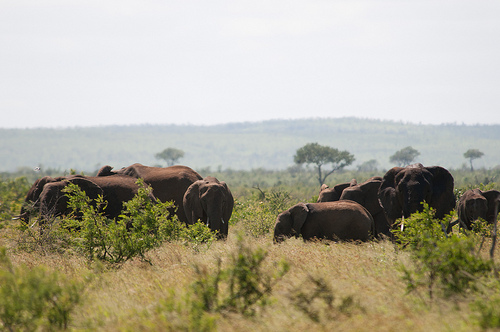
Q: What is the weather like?
A: It is cloudy.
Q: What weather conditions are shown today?
A: It is cloudy.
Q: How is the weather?
A: It is cloudy.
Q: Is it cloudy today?
A: Yes, it is cloudy.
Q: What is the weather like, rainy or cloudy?
A: It is cloudy.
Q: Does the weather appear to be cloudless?
A: No, it is cloudy.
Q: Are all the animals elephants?
A: Yes, all the animals are elephants.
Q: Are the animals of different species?
A: No, all the animals are elephants.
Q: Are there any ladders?
A: No, there are no ladders.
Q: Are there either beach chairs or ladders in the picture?
A: No, there are no ladders or beach chairs.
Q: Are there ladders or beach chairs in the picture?
A: No, there are no ladders or beach chairs.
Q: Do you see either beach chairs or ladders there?
A: No, there are no ladders or beach chairs.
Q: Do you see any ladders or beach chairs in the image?
A: No, there are no ladders or beach chairs.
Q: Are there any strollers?
A: No, there are no strollers.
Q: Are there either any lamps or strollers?
A: No, there are no strollers or lamps.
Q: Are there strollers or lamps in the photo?
A: No, there are no strollers or lamps.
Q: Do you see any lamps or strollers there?
A: No, there are no strollers or lamps.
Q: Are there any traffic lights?
A: No, there are no traffic lights.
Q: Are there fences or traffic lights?
A: No, there are no traffic lights or fences.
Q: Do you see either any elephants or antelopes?
A: Yes, there is an elephant.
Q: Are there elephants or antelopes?
A: Yes, there is an elephant.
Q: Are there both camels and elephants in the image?
A: No, there is an elephant but no camels.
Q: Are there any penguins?
A: No, there are no penguins.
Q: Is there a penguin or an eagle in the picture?
A: No, there are no penguins or eagles.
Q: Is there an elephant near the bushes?
A: Yes, there is an elephant near the bushes.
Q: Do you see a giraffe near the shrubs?
A: No, there is an elephant near the shrubs.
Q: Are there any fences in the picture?
A: No, there are no fences.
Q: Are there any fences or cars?
A: No, there are no fences or cars.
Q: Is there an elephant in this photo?
A: Yes, there is an elephant.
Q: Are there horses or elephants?
A: Yes, there is an elephant.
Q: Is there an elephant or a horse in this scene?
A: Yes, there is an elephant.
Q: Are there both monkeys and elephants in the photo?
A: No, there is an elephant but no monkeys.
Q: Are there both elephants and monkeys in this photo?
A: No, there is an elephant but no monkeys.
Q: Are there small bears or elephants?
A: Yes, there is a small elephant.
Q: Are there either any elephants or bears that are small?
A: Yes, the elephant is small.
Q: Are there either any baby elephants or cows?
A: Yes, there is a baby elephant.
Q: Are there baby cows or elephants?
A: Yes, there is a baby elephant.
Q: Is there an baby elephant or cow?
A: Yes, there is a baby elephant.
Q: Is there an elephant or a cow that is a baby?
A: Yes, the elephant is a baby.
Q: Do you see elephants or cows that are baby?
A: Yes, the elephant is a baby.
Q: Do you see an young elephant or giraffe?
A: Yes, there is a young elephant.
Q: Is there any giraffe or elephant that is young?
A: Yes, the elephant is young.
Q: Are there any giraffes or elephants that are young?
A: Yes, the elephant is young.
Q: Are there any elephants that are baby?
A: Yes, there is a baby elephant.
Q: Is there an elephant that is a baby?
A: Yes, there is an elephant that is a baby.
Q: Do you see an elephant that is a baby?
A: Yes, there is an elephant that is a baby.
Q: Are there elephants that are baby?
A: Yes, there is an elephant that is a baby.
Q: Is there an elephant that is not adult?
A: Yes, there is an baby elephant.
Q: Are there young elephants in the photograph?
A: Yes, there is a young elephant.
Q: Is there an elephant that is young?
A: Yes, there is an elephant that is young.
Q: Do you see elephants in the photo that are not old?
A: Yes, there is an young elephant.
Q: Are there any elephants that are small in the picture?
A: Yes, there is a small elephant.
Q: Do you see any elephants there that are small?
A: Yes, there is an elephant that is small.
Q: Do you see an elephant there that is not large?
A: Yes, there is a small elephant.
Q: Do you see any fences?
A: No, there are no fences.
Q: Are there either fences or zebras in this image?
A: No, there are no fences or zebras.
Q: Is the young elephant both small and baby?
A: Yes, the elephant is small and baby.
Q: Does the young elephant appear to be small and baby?
A: Yes, the elephant is small and baby.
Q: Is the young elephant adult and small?
A: No, the elephant is small but baby.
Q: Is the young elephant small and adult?
A: No, the elephant is small but baby.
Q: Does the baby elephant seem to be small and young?
A: Yes, the elephant is small and young.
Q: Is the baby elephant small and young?
A: Yes, the elephant is small and young.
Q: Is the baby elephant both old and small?
A: No, the elephant is small but young.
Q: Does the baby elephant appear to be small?
A: Yes, the elephant is small.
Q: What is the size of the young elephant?
A: The elephant is small.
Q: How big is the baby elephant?
A: The elephant is small.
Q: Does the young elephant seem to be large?
A: No, the elephant is small.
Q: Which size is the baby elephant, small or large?
A: The elephant is small.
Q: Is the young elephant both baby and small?
A: Yes, the elephant is a baby and small.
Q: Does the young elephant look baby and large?
A: No, the elephant is a baby but small.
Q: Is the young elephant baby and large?
A: No, the elephant is a baby but small.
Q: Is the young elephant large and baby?
A: No, the elephant is a baby but small.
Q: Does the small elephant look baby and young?
A: Yes, the elephant is a baby and young.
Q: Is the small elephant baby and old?
A: No, the elephant is a baby but young.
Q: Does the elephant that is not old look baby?
A: Yes, the elephant is a baby.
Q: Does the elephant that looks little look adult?
A: No, the elephant is a baby.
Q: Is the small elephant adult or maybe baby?
A: The elephant is a baby.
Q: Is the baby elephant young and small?
A: Yes, the elephant is young and small.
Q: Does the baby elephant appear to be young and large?
A: No, the elephant is young but small.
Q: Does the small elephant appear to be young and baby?
A: Yes, the elephant is young and baby.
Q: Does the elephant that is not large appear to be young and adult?
A: No, the elephant is young but baby.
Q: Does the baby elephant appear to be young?
A: Yes, the elephant is young.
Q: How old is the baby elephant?
A: The elephant is young.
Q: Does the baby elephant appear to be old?
A: No, the elephant is young.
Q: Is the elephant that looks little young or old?
A: The elephant is young.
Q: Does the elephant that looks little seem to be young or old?
A: The elephant is young.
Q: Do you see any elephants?
A: Yes, there is an elephant.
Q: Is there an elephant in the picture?
A: Yes, there is an elephant.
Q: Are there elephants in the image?
A: Yes, there is an elephant.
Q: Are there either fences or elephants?
A: Yes, there is an elephant.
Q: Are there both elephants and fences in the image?
A: No, there is an elephant but no fences.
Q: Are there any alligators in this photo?
A: No, there are no alligators.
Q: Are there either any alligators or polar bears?
A: No, there are no alligators or polar bears.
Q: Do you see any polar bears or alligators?
A: No, there are no alligators or polar bears.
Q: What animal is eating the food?
A: The elephant is eating the food.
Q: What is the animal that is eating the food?
A: The animal is an elephant.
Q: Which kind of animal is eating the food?
A: The animal is an elephant.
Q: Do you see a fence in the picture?
A: No, there are no fences.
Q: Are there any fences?
A: No, there are no fences.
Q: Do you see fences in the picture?
A: No, there are no fences.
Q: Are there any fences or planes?
A: No, there are no fences or planes.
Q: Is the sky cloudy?
A: Yes, the sky is cloudy.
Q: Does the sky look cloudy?
A: Yes, the sky is cloudy.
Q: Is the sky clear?
A: No, the sky is cloudy.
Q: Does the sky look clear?
A: No, the sky is cloudy.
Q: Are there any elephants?
A: Yes, there is an elephant.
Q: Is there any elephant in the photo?
A: Yes, there is an elephant.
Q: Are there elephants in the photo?
A: Yes, there is an elephant.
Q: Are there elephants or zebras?
A: Yes, there is an elephant.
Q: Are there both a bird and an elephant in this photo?
A: No, there is an elephant but no birds.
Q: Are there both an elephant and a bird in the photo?
A: No, there is an elephant but no birds.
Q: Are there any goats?
A: No, there are no goats.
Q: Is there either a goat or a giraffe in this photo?
A: No, there are no goats or giraffes.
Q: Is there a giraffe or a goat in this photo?
A: No, there are no goats or giraffes.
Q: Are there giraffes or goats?
A: No, there are no goats or giraffes.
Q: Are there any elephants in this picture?
A: Yes, there is an elephant.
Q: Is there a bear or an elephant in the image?
A: Yes, there is an elephant.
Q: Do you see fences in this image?
A: No, there are no fences.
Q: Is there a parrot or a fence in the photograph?
A: No, there are no fences or parrots.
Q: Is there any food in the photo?
A: Yes, there is food.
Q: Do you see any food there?
A: Yes, there is food.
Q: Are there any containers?
A: No, there are no containers.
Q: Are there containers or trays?
A: No, there are no containers or trays.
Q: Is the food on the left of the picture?
A: Yes, the food is on the left of the image.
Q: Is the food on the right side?
A: No, the food is on the left of the image.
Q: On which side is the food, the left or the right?
A: The food is on the left of the image.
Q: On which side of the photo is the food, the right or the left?
A: The food is on the left of the image.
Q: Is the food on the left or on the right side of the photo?
A: The food is on the left of the image.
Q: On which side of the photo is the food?
A: The food is on the left of the image.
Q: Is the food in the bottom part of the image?
A: Yes, the food is in the bottom of the image.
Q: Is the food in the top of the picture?
A: No, the food is in the bottom of the image.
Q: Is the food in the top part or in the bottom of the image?
A: The food is in the bottom of the image.